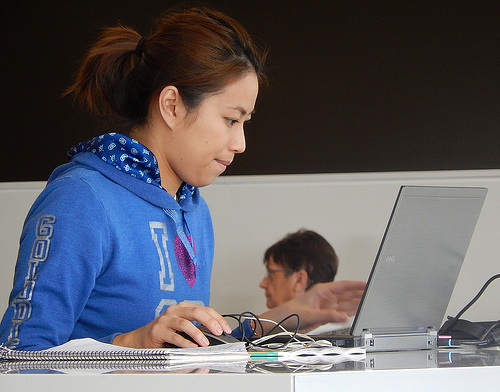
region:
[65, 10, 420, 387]
woman wearing blue sweatshirt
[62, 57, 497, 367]
woman working on laptop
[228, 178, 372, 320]
someone in background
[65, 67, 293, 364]
woman wearing blue shirt with white lettering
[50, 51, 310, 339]
woman wearing blue shirt with pink heart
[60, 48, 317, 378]
woman with hand on mouse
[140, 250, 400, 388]
wires on silver table by laptop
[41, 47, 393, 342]
woman with brown hair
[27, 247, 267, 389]
notebook on white table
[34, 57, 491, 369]
woman on laptop on white table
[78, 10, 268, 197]
girl with brown hair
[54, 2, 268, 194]
girl with hair in ponytail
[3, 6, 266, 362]
girl in blue hoodie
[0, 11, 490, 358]
girl working at laptop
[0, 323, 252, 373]
spiral bound notebook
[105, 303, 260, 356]
hand holding computer mouse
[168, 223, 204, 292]
heart design on sweatshirt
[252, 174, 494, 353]
laptop with top open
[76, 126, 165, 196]
patterned blue lining fabric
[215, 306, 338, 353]
computer peripheral device cables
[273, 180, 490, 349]
The computer used by woman in blue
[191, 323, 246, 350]
The mouse of the computer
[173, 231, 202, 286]
The heart on the sweatshirt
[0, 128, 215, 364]
The blue sweatshirt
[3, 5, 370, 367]
Woman in the blue sweatshirt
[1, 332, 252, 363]
The spiral notebook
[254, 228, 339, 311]
The person in the background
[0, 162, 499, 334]
The white wall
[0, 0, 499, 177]
The black portion of the wall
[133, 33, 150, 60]
The woman's hair tie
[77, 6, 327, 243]
a women with a pony tail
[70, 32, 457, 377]
a women on a lap top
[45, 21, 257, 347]
a women with a blue hoody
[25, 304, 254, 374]
a notebook on the table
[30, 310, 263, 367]
a spiral notebook open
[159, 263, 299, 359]
a hand on a mouse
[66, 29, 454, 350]
a women looking at the computer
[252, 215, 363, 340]
a women in the distance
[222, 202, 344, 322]
a women with glasses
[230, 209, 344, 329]
a woman with short hair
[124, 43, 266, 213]
face of a beautiful young woman.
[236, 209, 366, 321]
head of a person.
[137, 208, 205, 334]
words printed on a sweater.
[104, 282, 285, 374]
Woman holding a mouse.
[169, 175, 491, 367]
laptop computer sitting on a table.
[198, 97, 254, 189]
face of a pretty young lady.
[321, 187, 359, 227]
section of a wall.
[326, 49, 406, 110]
section of black wall.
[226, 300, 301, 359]
wires near a computer.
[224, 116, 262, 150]
a nose.